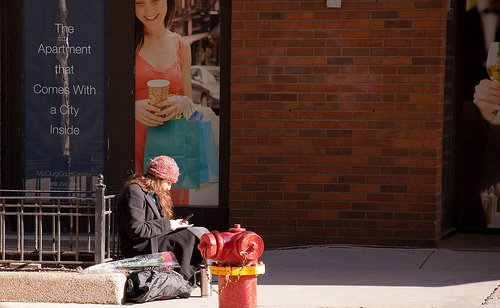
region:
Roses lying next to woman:
[115, 155, 185, 289]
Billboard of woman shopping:
[125, 3, 218, 153]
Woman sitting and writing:
[121, 153, 193, 263]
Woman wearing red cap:
[134, 150, 191, 197]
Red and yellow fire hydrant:
[191, 218, 273, 303]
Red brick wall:
[232, 8, 425, 240]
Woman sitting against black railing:
[98, 153, 185, 270]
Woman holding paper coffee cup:
[137, 1, 189, 156]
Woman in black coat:
[111, 147, 190, 262]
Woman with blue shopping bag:
[128, 4, 215, 151]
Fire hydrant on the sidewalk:
[202, 204, 257, 306]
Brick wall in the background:
[269, 78, 426, 235]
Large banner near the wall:
[123, 9, 240, 204]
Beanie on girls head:
[145, 147, 190, 191]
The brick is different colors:
[275, 48, 436, 232]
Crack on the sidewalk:
[452, 257, 497, 301]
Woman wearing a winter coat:
[122, 175, 211, 270]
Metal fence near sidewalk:
[0, 178, 121, 306]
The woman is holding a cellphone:
[175, 201, 202, 232]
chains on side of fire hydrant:
[197, 234, 252, 303]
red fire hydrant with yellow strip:
[196, 223, 269, 305]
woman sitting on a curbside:
[115, 158, 212, 289]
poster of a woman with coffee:
[132, 0, 221, 209]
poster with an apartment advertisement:
[20, 1, 106, 205]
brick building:
[227, 0, 459, 245]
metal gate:
[0, 181, 120, 263]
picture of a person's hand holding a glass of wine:
[472, 39, 498, 129]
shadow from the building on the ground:
[196, 246, 497, 283]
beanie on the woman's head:
[147, 158, 178, 182]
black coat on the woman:
[118, 181, 169, 256]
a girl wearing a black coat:
[113, 154, 213, 285]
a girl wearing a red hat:
[116, 154, 213, 286]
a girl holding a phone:
[115, 153, 217, 288]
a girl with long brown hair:
[118, 153, 213, 293]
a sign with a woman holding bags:
[129, 0, 221, 208]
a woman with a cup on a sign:
[130, 1, 222, 209]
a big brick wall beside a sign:
[229, 1, 440, 245]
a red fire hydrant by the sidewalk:
[195, 223, 266, 307]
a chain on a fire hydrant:
[198, 248, 250, 293]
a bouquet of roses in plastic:
[73, 250, 180, 275]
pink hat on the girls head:
[143, 153, 183, 185]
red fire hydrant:
[198, 225, 266, 306]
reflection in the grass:
[54, 4, 76, 161]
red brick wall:
[244, 14, 438, 228]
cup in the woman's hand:
[145, 77, 172, 122]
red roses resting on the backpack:
[82, 253, 178, 279]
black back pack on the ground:
[122, 269, 195, 303]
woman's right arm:
[126, 182, 170, 242]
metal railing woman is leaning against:
[2, 179, 126, 279]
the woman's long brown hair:
[122, 167, 176, 224]